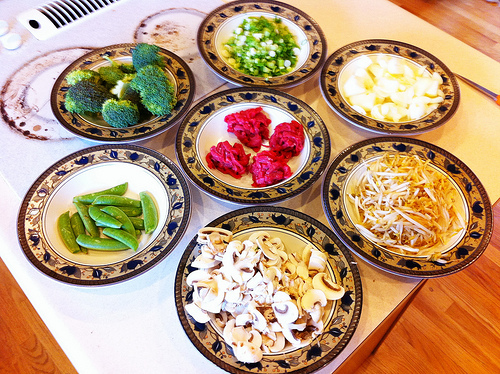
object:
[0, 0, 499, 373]
table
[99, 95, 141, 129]
broccoli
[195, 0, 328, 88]
dining plate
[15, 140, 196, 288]
bowl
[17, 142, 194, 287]
floral print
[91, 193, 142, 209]
snap peas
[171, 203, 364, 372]
plate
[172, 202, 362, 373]
trim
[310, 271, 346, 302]
mushroom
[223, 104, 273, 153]
food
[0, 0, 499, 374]
counter